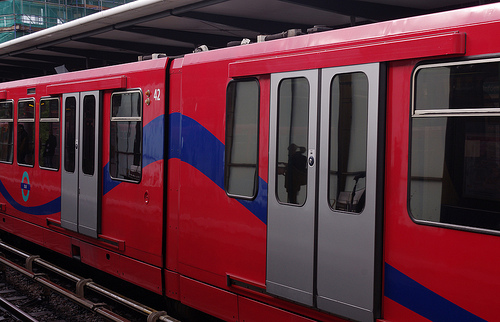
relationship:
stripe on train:
[0, 111, 486, 322] [84, 25, 441, 276]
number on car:
[154, 88, 161, 100] [0, 0, 500, 322]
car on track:
[0, 0, 500, 322] [4, 243, 62, 308]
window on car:
[105, 85, 145, 184] [0, 0, 500, 322]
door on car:
[278, 77, 362, 309] [0, 0, 500, 322]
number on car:
[152, 86, 158, 101] [0, 0, 500, 322]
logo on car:
[16, 174, 34, 203] [0, 0, 500, 322]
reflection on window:
[331, 80, 361, 214] [326, 69, 371, 215]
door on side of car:
[265, 62, 389, 322] [0, 0, 500, 322]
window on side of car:
[222, 73, 262, 196] [0, 0, 500, 322]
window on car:
[409, 62, 500, 233] [0, 59, 166, 296]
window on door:
[324, 72, 373, 217] [313, 59, 382, 316]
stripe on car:
[126, 93, 476, 320] [0, 0, 500, 322]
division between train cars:
[162, 62, 167, 298] [3, 7, 496, 319]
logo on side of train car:
[21, 171, 30, 202] [4, 62, 171, 302]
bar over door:
[225, 29, 467, 69] [276, 69, 388, 319]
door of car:
[265, 62, 389, 322] [0, 0, 500, 322]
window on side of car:
[400, 59, 498, 232] [0, 0, 500, 322]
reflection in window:
[282, 142, 306, 202] [272, 77, 308, 206]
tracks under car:
[6, 255, 122, 319] [0, 0, 500, 322]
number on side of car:
[154, 88, 161, 100] [0, 0, 500, 322]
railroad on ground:
[1, 281, 48, 320] [5, 270, 103, 316]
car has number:
[0, 0, 500, 322] [150, 86, 161, 101]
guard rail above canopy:
[0, 12, 72, 30] [7, 9, 199, 52]